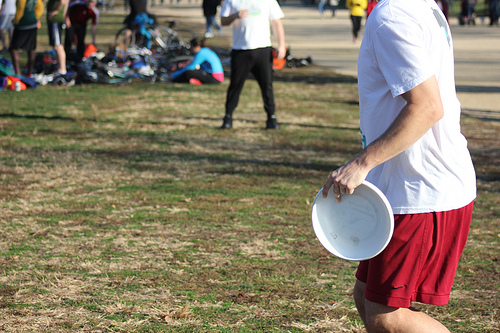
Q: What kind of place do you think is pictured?
A: It is a park.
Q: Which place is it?
A: It is a park.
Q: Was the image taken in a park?
A: Yes, it was taken in a park.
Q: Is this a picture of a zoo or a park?
A: It is showing a park.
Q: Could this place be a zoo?
A: No, it is a park.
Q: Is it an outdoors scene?
A: Yes, it is outdoors.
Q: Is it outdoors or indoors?
A: It is outdoors.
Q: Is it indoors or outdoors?
A: It is outdoors.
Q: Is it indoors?
A: No, it is outdoors.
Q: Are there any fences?
A: No, there are no fences.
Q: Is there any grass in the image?
A: Yes, there is grass.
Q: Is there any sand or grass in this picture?
A: Yes, there is grass.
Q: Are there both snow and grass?
A: No, there is grass but no snow.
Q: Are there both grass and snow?
A: No, there is grass but no snow.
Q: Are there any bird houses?
A: No, there are no bird houses.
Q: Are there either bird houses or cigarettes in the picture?
A: No, there are no bird houses or cigarettes.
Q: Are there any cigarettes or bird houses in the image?
A: No, there are no bird houses or cigarettes.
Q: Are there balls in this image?
A: No, there are no balls.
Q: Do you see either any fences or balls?
A: No, there are no balls or fences.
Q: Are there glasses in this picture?
A: No, there are no glasses.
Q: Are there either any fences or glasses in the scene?
A: No, there are no glasses or fences.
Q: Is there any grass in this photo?
A: Yes, there is grass.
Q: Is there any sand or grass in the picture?
A: Yes, there is grass.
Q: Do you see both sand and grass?
A: No, there is grass but no sand.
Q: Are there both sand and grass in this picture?
A: No, there is grass but no sand.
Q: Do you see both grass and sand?
A: No, there is grass but no sand.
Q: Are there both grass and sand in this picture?
A: No, there is grass but no sand.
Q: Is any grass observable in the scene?
A: Yes, there is grass.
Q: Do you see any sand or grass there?
A: Yes, there is grass.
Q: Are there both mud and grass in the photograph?
A: No, there is grass but no mud.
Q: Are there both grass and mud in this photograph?
A: No, there is grass but no mud.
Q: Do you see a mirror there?
A: No, there are no mirrors.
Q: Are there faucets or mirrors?
A: No, there are no mirrors or faucets.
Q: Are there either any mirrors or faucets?
A: No, there are no mirrors or faucets.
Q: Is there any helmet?
A: No, there are no helmets.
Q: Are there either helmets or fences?
A: No, there are no helmets or fences.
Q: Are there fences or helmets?
A: No, there are no helmets or fences.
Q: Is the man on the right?
A: Yes, the man is on the right of the image.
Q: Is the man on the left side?
A: No, the man is on the right of the image.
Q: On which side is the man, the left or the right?
A: The man is on the right of the image.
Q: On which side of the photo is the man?
A: The man is on the right of the image.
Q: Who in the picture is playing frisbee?
A: The man is playing frisbee.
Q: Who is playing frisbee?
A: The man is playing frisbee.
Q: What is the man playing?
A: The man is playing frisbee.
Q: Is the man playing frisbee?
A: Yes, the man is playing frisbee.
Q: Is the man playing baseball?
A: No, the man is playing frisbee.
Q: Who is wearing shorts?
A: The man is wearing shorts.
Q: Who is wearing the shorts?
A: The man is wearing shorts.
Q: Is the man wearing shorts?
A: Yes, the man is wearing shorts.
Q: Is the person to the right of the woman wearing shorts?
A: Yes, the man is wearing shorts.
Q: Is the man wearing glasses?
A: No, the man is wearing shorts.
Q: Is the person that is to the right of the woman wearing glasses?
A: No, the man is wearing shorts.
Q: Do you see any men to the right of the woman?
A: Yes, there is a man to the right of the woman.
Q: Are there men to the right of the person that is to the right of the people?
A: Yes, there is a man to the right of the woman.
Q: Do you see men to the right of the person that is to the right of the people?
A: Yes, there is a man to the right of the woman.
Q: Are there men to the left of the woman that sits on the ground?
A: No, the man is to the right of the woman.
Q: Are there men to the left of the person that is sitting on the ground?
A: No, the man is to the right of the woman.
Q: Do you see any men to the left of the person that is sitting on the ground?
A: No, the man is to the right of the woman.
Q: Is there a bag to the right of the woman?
A: No, there is a man to the right of the woman.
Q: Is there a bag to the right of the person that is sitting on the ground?
A: No, there is a man to the right of the woman.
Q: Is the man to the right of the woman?
A: Yes, the man is to the right of the woman.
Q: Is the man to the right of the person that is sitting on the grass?
A: Yes, the man is to the right of the woman.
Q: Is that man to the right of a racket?
A: No, the man is to the right of the woman.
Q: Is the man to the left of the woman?
A: No, the man is to the right of the woman.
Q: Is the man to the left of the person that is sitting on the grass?
A: No, the man is to the right of the woman.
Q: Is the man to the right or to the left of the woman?
A: The man is to the right of the woman.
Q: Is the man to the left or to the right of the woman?
A: The man is to the right of the woman.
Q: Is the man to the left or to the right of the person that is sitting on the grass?
A: The man is to the right of the woman.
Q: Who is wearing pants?
A: The man is wearing pants.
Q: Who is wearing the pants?
A: The man is wearing pants.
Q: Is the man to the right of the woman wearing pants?
A: Yes, the man is wearing pants.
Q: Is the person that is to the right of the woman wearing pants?
A: Yes, the man is wearing pants.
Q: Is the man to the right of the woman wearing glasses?
A: No, the man is wearing pants.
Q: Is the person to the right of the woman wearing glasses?
A: No, the man is wearing pants.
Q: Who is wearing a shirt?
A: The man is wearing a shirt.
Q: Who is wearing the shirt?
A: The man is wearing a shirt.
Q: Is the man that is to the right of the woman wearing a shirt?
A: Yes, the man is wearing a shirt.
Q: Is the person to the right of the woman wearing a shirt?
A: Yes, the man is wearing a shirt.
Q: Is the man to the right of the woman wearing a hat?
A: No, the man is wearing a shirt.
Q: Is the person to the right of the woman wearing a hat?
A: No, the man is wearing a shirt.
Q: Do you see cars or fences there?
A: No, there are no fences or cars.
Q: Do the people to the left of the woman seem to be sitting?
A: Yes, the people are sitting.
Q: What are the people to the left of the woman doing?
A: The people are sitting.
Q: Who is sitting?
A: The people are sitting.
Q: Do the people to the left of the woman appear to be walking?
A: No, the people are sitting.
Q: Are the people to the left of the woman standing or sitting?
A: The people are sitting.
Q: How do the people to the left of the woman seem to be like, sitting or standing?
A: The people are sitting.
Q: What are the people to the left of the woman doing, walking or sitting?
A: The people are sitting.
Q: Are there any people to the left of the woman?
A: Yes, there are people to the left of the woman.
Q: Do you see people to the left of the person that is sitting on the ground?
A: Yes, there are people to the left of the woman.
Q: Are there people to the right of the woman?
A: No, the people are to the left of the woman.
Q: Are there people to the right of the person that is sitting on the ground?
A: No, the people are to the left of the woman.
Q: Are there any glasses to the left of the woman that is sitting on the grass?
A: No, there are people to the left of the woman.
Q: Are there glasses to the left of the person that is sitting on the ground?
A: No, there are people to the left of the woman.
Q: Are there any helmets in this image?
A: No, there are no helmets.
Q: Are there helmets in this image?
A: No, there are no helmets.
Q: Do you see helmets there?
A: No, there are no helmets.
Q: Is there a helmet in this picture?
A: No, there are no helmets.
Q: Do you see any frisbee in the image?
A: Yes, there is a frisbee.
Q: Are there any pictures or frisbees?
A: Yes, there is a frisbee.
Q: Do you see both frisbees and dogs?
A: No, there is a frisbee but no dogs.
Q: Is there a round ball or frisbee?
A: Yes, there is a round frisbee.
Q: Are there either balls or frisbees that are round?
A: Yes, the frisbee is round.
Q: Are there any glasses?
A: No, there are no glasses.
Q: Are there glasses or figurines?
A: No, there are no glasses or figurines.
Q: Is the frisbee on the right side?
A: Yes, the frisbee is on the right of the image.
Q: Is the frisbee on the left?
A: No, the frisbee is on the right of the image.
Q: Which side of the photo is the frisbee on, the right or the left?
A: The frisbee is on the right of the image.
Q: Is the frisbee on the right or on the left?
A: The frisbee is on the right of the image.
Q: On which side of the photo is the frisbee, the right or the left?
A: The frisbee is on the right of the image.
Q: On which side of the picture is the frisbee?
A: The frisbee is on the right of the image.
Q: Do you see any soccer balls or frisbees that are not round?
A: No, there is a frisbee but it is round.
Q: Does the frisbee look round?
A: Yes, the frisbee is round.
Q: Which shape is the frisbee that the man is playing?
A: The frisbee is round.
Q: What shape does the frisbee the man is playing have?
A: The frisbee has round shape.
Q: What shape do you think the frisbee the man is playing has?
A: The frisbee has round shape.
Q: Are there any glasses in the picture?
A: No, there are no glasses.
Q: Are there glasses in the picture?
A: No, there are no glasses.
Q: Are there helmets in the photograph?
A: No, there are no helmets.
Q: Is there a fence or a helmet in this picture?
A: No, there are no helmets or fences.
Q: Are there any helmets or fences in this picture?
A: No, there are no helmets or fences.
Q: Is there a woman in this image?
A: Yes, there is a woman.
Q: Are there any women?
A: Yes, there is a woman.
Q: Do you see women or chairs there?
A: Yes, there is a woman.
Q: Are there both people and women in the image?
A: Yes, there are both a woman and people.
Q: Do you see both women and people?
A: Yes, there are both a woman and people.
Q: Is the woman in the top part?
A: Yes, the woman is in the top of the image.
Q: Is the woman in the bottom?
A: No, the woman is in the top of the image.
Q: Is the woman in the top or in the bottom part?
A: The woman is in the top of the image.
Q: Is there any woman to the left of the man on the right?
A: Yes, there is a woman to the left of the man.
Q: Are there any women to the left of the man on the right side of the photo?
A: Yes, there is a woman to the left of the man.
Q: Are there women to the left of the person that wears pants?
A: Yes, there is a woman to the left of the man.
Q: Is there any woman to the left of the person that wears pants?
A: Yes, there is a woman to the left of the man.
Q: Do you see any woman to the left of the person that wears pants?
A: Yes, there is a woman to the left of the man.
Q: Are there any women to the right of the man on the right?
A: No, the woman is to the left of the man.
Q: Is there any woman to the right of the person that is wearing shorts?
A: No, the woman is to the left of the man.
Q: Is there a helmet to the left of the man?
A: No, there is a woman to the left of the man.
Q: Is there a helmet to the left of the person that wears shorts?
A: No, there is a woman to the left of the man.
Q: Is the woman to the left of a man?
A: Yes, the woman is to the left of a man.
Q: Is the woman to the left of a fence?
A: No, the woman is to the left of a man.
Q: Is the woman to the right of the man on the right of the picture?
A: No, the woman is to the left of the man.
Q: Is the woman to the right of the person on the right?
A: No, the woman is to the left of the man.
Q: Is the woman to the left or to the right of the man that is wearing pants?
A: The woman is to the left of the man.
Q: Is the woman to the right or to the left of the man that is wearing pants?
A: The woman is to the left of the man.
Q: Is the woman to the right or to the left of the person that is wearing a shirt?
A: The woman is to the left of the man.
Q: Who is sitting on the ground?
A: The woman is sitting on the ground.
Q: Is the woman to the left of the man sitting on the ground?
A: Yes, the woman is sitting on the ground.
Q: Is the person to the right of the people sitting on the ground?
A: Yes, the woman is sitting on the ground.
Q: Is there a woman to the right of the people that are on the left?
A: Yes, there is a woman to the right of the people.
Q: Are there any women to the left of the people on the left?
A: No, the woman is to the right of the people.